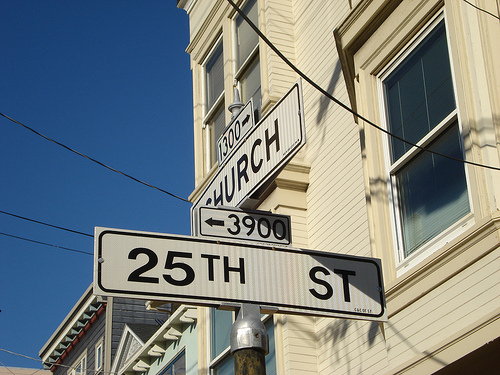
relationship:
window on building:
[347, 37, 480, 242] [263, 4, 406, 349]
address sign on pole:
[91, 225, 386, 321] [227, 323, 267, 374]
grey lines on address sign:
[258, 252, 308, 302] [91, 225, 386, 321]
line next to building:
[24, 107, 364, 313] [149, 30, 496, 367]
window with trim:
[347, 0, 475, 265] [380, 206, 486, 273]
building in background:
[174, 0, 499, 370] [17, 139, 256, 277]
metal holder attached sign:
[47, 157, 437, 353] [82, 152, 371, 323]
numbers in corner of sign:
[354, 307, 381, 319] [90, 227, 390, 319]